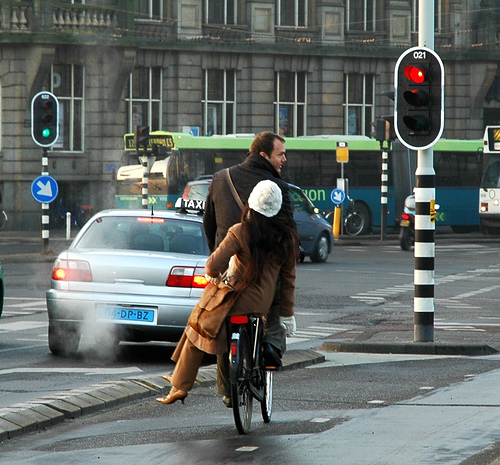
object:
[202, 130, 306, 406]
man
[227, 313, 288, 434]
bike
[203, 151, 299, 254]
jacket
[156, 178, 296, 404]
woman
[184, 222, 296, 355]
coat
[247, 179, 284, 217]
hat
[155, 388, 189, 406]
shoes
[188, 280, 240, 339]
bag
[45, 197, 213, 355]
car